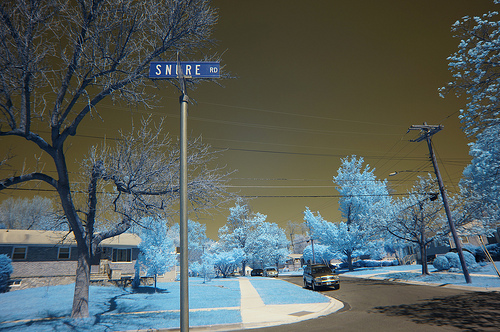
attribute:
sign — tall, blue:
[151, 48, 242, 96]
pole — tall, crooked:
[166, 95, 212, 328]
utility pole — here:
[394, 111, 476, 329]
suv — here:
[300, 267, 368, 304]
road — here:
[353, 284, 427, 326]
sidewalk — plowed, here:
[232, 272, 266, 331]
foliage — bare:
[47, 31, 189, 137]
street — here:
[353, 272, 402, 328]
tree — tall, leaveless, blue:
[343, 163, 383, 209]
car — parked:
[263, 264, 281, 293]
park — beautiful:
[332, 187, 461, 325]